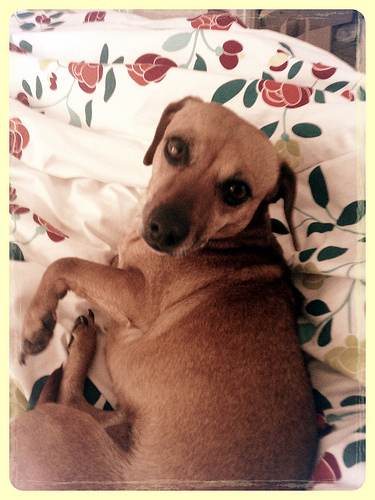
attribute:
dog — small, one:
[12, 92, 324, 492]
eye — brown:
[162, 131, 194, 168]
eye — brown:
[215, 172, 256, 208]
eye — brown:
[215, 175, 257, 213]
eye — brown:
[158, 132, 194, 171]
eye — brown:
[217, 178, 255, 209]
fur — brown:
[168, 340, 223, 425]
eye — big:
[162, 132, 196, 170]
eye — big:
[214, 175, 259, 210]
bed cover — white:
[9, 11, 363, 488]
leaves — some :
[311, 156, 369, 268]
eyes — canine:
[168, 129, 255, 210]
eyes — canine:
[165, 134, 264, 214]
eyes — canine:
[162, 130, 258, 212]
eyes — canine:
[165, 134, 257, 211]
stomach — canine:
[102, 329, 213, 413]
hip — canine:
[13, 398, 137, 475]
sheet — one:
[281, 37, 362, 492]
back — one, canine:
[262, 282, 326, 498]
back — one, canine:
[274, 296, 332, 494]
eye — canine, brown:
[225, 170, 248, 208]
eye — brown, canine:
[161, 129, 193, 169]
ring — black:
[218, 168, 252, 213]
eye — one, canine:
[217, 169, 253, 205]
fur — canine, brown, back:
[185, 348, 254, 470]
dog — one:
[64, 92, 323, 469]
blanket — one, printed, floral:
[25, 23, 345, 93]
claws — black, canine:
[65, 310, 103, 356]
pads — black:
[20, 313, 57, 360]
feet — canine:
[16, 281, 108, 362]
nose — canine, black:
[139, 207, 188, 254]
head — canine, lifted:
[133, 85, 278, 269]